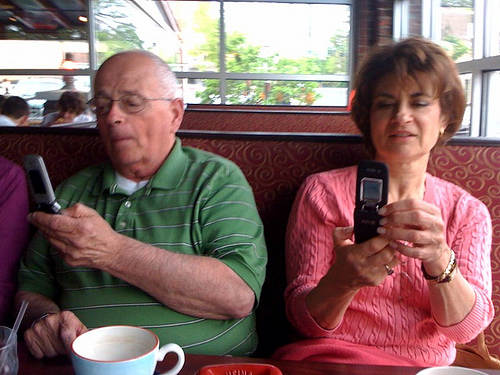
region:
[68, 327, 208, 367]
the coffee cup is white in color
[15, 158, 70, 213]
the man is on the phone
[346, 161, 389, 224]
the lady is on the phone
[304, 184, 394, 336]
the lady has the pink shirt on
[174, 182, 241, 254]
the man has a green shirt on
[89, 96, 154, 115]
the man has on glasses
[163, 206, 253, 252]
the man shirt is striped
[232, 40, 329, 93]
the windows in the back is huge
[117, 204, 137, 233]
the man has 2 buttons on his shirt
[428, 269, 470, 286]
the lady has some jewerly on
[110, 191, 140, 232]
Two buttons on a green shirt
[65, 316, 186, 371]
A white coffee mug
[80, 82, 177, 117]
A pair of glasses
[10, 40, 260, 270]
A man looking at his cell phone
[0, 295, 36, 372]
Plastic straw in a glass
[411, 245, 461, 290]
Bracelets around a wrist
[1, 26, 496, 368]
A man and woman sitting in a booth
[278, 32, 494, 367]
Woman is wearing a pink sweater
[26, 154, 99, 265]
The man is using his phone.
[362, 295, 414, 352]
The sweater is pink.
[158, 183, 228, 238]
The shirt is green.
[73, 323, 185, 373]
A coffee mug is on the table.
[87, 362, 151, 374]
The mug is blue.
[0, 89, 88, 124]
Diners are seated in the background.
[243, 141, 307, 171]
The restaurant booth is patterned.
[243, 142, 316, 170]
The booth is red.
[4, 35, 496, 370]
couple seated in restaurant booth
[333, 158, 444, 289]
two hands on flip phone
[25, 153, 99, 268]
flip phone in hand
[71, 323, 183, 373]
coffee cup with handle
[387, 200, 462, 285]
bracelet on woman's wrist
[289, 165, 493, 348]
pink sweater with vertical designs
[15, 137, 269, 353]
green shirt with stripes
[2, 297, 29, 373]
straw resting on glass rim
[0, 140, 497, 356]
red bench with gold design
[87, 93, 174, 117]
glasses on man's nose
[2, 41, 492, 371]
both are using the phone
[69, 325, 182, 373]
a white and blue empty cup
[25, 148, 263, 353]
he is wearing a green polo shirt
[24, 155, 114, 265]
his hand holding the phone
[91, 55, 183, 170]
the head of the man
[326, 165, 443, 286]
her two hands holding the phone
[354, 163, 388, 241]
this is not a smartphone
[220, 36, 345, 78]
trees in the distance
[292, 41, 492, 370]
she is sending a text message